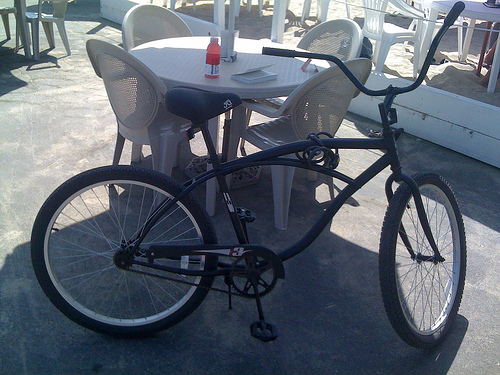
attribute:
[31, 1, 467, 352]
bike — black, big, leaning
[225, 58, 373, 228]
chair — white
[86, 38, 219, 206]
chair — white, plastic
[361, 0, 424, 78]
chair — white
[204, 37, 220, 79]
bottle — red, pink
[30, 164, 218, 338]
wheel — black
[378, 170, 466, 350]
wheel — black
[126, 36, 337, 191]
table — round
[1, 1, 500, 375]
ground — clean, grey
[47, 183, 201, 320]
wiring — thin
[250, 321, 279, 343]
pedal — black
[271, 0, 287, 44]
pole — white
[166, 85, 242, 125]
seat — black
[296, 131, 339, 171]
lock — black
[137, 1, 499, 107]
sand — white